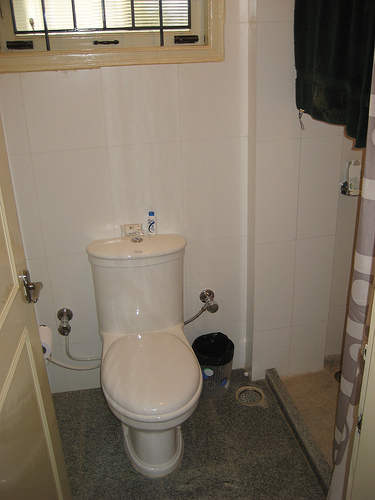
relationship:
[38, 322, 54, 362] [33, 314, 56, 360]
toilet paper on holder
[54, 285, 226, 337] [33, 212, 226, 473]
plumbing for toilet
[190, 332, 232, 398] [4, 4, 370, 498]
trashcan in bathroom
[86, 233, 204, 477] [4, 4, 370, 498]
toilet in center of bathroom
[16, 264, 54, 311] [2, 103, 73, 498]
handle on door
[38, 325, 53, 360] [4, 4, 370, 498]
toilet paper in bathroom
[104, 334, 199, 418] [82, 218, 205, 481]
toilet seat on toilet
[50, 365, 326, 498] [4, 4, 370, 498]
floor in bathroom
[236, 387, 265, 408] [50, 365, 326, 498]
drain on floor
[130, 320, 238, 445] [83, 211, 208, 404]
lid on toilet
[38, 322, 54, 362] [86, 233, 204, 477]
toilet paper next to toilet